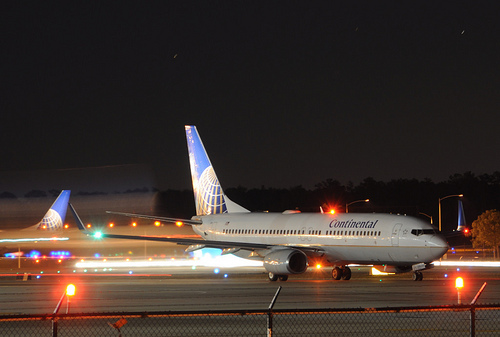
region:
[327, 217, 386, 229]
Continental brand on plane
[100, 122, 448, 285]
large passenger plane landing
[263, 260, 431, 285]
landing gear is down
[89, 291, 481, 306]
barb wire on top of fence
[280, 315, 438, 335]
cyclone fence at airport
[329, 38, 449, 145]
dark skies at night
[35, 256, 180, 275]
blue and red runway lights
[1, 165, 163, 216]
glare from lights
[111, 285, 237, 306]
asphalt on runway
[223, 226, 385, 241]
lots of windows on side of plane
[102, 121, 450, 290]
Plane on runway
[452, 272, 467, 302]
Bright orange light on top of fence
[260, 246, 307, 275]
Large white jet engine on wing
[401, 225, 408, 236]
Star next to white door of plane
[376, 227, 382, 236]
Small window by white door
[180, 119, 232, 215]
Tail of plane is illuminated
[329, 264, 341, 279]
Round black tire of plane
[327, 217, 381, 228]
Continental logo on plane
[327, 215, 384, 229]
Continental logo is blue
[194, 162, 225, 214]
Globe printed on tail of plane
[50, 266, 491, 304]
the lights on the runway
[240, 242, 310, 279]
the engine on the plane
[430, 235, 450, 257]
the nose of the plane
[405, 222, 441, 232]
the cockpit on the plane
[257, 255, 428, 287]
the landing gear is down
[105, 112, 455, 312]
the plane on the runway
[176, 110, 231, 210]
the tail of the plane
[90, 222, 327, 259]
the wing of the plane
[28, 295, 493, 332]
the fence beside the runway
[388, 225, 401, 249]
the hatch on the plane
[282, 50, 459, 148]
the sky is pitch black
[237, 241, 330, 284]
the engine of the plane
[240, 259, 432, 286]
the landing gear of the plane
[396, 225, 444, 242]
the cockpit of the plane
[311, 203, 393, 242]
continental written on the plane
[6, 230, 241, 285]
the lights on the runway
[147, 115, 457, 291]
plane parked on tarmac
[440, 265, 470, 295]
glow of light on tarmac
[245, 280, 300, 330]
pole on chain link fence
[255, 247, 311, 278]
jet engine under wing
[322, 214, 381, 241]
name of airline on plane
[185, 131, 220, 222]
logo on plane tail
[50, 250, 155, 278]
lights on airport tarmac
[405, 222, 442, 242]
windows on front of plane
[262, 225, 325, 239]
windows on side of plane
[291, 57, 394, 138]
dark gray of night time sky